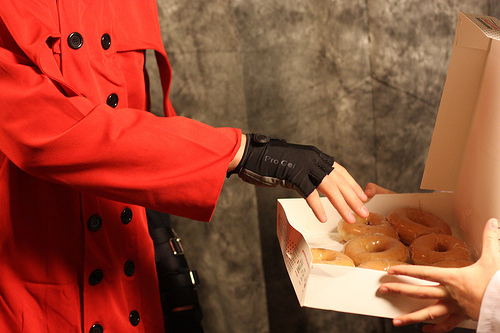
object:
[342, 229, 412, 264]
donut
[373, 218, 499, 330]
hand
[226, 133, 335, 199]
glove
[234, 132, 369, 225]
person's hand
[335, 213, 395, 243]
donut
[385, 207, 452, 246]
donut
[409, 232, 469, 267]
donut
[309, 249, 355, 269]
donut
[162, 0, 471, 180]
wall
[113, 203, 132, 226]
button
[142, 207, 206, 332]
purse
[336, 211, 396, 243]
donuts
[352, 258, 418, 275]
doughnuts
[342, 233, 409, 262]
dounut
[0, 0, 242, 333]
jacket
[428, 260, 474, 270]
donuts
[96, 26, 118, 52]
button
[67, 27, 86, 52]
button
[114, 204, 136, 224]
button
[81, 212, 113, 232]
button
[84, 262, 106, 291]
button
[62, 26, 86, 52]
button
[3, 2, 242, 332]
coat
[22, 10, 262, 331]
coat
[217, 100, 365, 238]
hand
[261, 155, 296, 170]
text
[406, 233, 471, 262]
donuts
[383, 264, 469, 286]
fingers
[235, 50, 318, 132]
background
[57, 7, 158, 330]
box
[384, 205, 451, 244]
donuts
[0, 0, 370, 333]
person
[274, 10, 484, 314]
box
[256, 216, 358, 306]
box